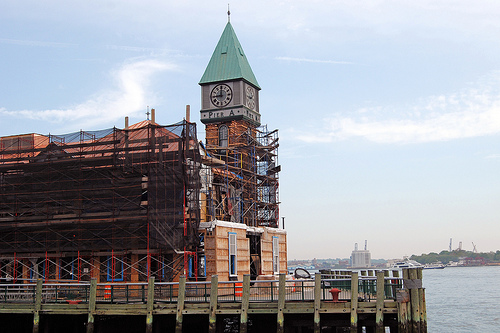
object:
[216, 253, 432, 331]
pier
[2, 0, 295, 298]
building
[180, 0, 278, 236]
tower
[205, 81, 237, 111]
clock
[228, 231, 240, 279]
window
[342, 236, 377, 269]
building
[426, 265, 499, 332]
water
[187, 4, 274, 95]
roof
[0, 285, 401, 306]
barrel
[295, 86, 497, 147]
cloud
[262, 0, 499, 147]
sky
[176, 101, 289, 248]
scaffolding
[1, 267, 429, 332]
dock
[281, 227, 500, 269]
distance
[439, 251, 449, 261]
trees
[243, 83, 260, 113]
clock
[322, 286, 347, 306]
hydrant